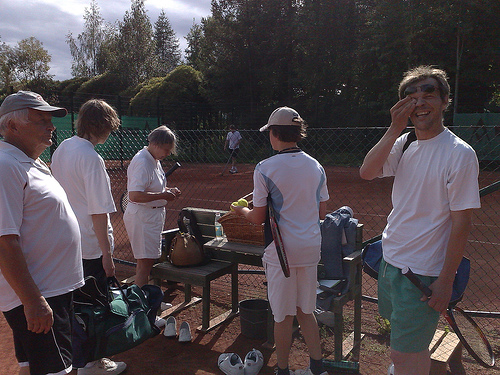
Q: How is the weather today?
A: It is cloudy.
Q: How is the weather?
A: It is cloudy.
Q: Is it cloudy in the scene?
A: Yes, it is cloudy.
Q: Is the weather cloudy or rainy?
A: It is cloudy.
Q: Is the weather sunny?
A: No, it is cloudy.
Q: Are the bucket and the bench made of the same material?
A: Yes, both the bucket and the bench are made of wood.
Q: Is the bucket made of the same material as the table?
A: Yes, both the bucket and the table are made of wood.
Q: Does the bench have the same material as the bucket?
A: Yes, both the bench and the bucket are made of wood.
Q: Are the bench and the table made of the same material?
A: Yes, both the bench and the table are made of wood.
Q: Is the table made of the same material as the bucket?
A: Yes, both the table and the bucket are made of wood.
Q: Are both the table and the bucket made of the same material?
A: Yes, both the table and the bucket are made of wood.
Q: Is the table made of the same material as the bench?
A: Yes, both the table and the bench are made of wood.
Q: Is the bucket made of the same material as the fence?
A: No, the bucket is made of wood and the fence is made of metal.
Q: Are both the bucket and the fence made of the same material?
A: No, the bucket is made of wood and the fence is made of metal.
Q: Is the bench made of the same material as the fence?
A: No, the bench is made of wood and the fence is made of metal.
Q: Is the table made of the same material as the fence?
A: No, the table is made of wood and the fence is made of metal.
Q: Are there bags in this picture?
A: Yes, there is a bag.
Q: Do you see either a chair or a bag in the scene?
A: Yes, there is a bag.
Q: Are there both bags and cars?
A: No, there is a bag but no cars.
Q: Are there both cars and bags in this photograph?
A: No, there is a bag but no cars.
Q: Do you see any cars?
A: No, there are no cars.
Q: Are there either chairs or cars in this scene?
A: No, there are no cars or chairs.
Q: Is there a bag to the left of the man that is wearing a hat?
A: Yes, there is a bag to the left of the man.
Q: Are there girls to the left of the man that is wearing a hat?
A: No, there is a bag to the left of the man.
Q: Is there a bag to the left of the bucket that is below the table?
A: Yes, there is a bag to the left of the bucket.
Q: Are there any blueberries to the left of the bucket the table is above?
A: No, there is a bag to the left of the bucket.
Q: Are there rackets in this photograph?
A: Yes, there is a racket.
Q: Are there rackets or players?
A: Yes, there is a racket.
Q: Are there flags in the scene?
A: No, there are no flags.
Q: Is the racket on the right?
A: Yes, the racket is on the right of the image.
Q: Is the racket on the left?
A: No, the racket is on the right of the image.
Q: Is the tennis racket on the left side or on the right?
A: The tennis racket is on the right of the image.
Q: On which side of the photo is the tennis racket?
A: The tennis racket is on the right of the image.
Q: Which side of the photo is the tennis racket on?
A: The tennis racket is on the right of the image.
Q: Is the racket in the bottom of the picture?
A: Yes, the racket is in the bottom of the image.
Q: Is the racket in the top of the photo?
A: No, the racket is in the bottom of the image.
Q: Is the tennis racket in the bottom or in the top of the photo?
A: The tennis racket is in the bottom of the image.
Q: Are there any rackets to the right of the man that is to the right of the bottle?
A: Yes, there is a racket to the right of the man.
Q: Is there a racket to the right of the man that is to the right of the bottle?
A: Yes, there is a racket to the right of the man.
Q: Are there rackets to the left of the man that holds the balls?
A: No, the racket is to the right of the man.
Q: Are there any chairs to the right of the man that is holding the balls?
A: No, there is a racket to the right of the man.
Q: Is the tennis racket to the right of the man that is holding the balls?
A: Yes, the tennis racket is to the right of the man.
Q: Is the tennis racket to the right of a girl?
A: No, the tennis racket is to the right of the man.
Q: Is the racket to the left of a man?
A: No, the racket is to the right of a man.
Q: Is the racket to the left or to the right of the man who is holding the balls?
A: The racket is to the right of the man.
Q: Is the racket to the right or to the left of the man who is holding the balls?
A: The racket is to the right of the man.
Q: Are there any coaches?
A: No, there are no coaches.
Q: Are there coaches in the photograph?
A: No, there are no coaches.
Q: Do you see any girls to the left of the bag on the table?
A: No, there is a man to the left of the bag.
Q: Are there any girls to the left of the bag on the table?
A: No, there is a man to the left of the bag.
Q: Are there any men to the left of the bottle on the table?
A: Yes, there is a man to the left of the bottle.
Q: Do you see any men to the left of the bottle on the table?
A: Yes, there is a man to the left of the bottle.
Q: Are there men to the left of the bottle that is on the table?
A: Yes, there is a man to the left of the bottle.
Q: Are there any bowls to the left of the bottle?
A: No, there is a man to the left of the bottle.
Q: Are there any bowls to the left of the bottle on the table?
A: No, there is a man to the left of the bottle.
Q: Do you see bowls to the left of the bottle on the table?
A: No, there is a man to the left of the bottle.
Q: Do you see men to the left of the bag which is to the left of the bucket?
A: Yes, there is a man to the left of the bag.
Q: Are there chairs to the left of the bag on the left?
A: No, there is a man to the left of the bag.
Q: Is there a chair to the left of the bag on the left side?
A: No, there is a man to the left of the bag.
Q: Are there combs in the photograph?
A: No, there are no combs.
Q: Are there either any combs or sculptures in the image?
A: No, there are no combs or sculptures.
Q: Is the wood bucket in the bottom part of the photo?
A: Yes, the bucket is in the bottom of the image.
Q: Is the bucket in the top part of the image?
A: No, the bucket is in the bottom of the image.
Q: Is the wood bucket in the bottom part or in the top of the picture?
A: The bucket is in the bottom of the image.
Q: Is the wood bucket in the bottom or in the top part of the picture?
A: The bucket is in the bottom of the image.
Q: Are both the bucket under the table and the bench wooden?
A: Yes, both the bucket and the bench are wooden.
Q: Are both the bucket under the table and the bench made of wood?
A: Yes, both the bucket and the bench are made of wood.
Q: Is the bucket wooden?
A: Yes, the bucket is wooden.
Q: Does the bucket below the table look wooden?
A: Yes, the bucket is wooden.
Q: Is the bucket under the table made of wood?
A: Yes, the bucket is made of wood.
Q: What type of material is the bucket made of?
A: The bucket is made of wood.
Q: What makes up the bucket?
A: The bucket is made of wood.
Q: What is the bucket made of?
A: The bucket is made of wood.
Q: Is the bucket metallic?
A: No, the bucket is wooden.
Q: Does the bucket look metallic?
A: No, the bucket is wooden.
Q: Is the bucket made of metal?
A: No, the bucket is made of wood.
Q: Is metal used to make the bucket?
A: No, the bucket is made of wood.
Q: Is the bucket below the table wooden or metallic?
A: The bucket is wooden.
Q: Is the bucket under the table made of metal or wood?
A: The bucket is made of wood.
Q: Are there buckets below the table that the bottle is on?
A: Yes, there is a bucket below the table.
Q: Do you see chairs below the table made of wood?
A: No, there is a bucket below the table.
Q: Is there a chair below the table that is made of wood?
A: No, there is a bucket below the table.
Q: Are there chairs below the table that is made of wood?
A: No, there is a bucket below the table.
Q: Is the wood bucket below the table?
A: Yes, the bucket is below the table.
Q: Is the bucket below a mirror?
A: No, the bucket is below the table.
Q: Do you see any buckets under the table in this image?
A: Yes, there is a bucket under the table.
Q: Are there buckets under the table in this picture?
A: Yes, there is a bucket under the table.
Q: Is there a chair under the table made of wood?
A: No, there is a bucket under the table.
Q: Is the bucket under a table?
A: Yes, the bucket is under a table.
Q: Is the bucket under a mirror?
A: No, the bucket is under a table.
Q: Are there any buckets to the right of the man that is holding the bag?
A: Yes, there is a bucket to the right of the man.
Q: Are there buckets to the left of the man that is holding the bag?
A: No, the bucket is to the right of the man.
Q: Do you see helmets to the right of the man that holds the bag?
A: No, there is a bucket to the right of the man.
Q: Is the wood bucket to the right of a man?
A: Yes, the bucket is to the right of a man.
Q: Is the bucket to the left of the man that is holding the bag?
A: No, the bucket is to the right of the man.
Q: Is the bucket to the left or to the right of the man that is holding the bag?
A: The bucket is to the right of the man.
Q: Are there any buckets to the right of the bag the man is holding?
A: Yes, there is a bucket to the right of the bag.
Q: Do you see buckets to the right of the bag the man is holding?
A: Yes, there is a bucket to the right of the bag.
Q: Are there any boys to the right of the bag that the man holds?
A: No, there is a bucket to the right of the bag.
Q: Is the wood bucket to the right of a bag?
A: Yes, the bucket is to the right of a bag.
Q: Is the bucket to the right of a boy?
A: No, the bucket is to the right of a bag.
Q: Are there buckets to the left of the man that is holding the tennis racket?
A: Yes, there is a bucket to the left of the man.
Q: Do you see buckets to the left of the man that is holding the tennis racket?
A: Yes, there is a bucket to the left of the man.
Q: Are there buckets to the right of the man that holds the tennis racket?
A: No, the bucket is to the left of the man.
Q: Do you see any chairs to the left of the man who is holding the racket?
A: No, there is a bucket to the left of the man.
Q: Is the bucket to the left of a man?
A: Yes, the bucket is to the left of a man.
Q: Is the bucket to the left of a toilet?
A: No, the bucket is to the left of a man.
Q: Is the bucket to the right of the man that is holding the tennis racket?
A: No, the bucket is to the left of the man.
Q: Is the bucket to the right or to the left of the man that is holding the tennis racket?
A: The bucket is to the left of the man.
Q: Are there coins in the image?
A: No, there are no coins.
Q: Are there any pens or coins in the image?
A: No, there are no coins or pens.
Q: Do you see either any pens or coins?
A: No, there are no coins or pens.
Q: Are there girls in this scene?
A: No, there are no girls.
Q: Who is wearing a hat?
A: The man is wearing a hat.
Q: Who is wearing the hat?
A: The man is wearing a hat.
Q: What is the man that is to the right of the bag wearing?
A: The man is wearing a hat.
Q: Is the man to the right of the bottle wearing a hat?
A: Yes, the man is wearing a hat.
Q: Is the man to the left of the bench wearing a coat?
A: No, the man is wearing a hat.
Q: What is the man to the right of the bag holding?
A: The man is holding the balls.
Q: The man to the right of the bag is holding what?
A: The man is holding the balls.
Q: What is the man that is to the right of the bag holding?
A: The man is holding the balls.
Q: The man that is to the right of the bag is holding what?
A: The man is holding the balls.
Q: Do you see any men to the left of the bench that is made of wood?
A: Yes, there is a man to the left of the bench.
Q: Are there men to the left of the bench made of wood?
A: Yes, there is a man to the left of the bench.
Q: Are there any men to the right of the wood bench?
A: No, the man is to the left of the bench.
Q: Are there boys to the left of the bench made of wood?
A: No, there is a man to the left of the bench.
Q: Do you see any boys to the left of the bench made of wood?
A: No, there is a man to the left of the bench.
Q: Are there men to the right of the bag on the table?
A: Yes, there is a man to the right of the bag.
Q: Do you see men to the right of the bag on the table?
A: Yes, there is a man to the right of the bag.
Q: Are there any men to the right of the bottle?
A: Yes, there is a man to the right of the bottle.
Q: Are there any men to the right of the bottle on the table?
A: Yes, there is a man to the right of the bottle.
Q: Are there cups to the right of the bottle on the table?
A: No, there is a man to the right of the bottle.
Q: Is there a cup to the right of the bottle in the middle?
A: No, there is a man to the right of the bottle.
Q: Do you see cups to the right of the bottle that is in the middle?
A: No, there is a man to the right of the bottle.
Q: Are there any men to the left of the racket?
A: Yes, there is a man to the left of the racket.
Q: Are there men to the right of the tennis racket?
A: No, the man is to the left of the tennis racket.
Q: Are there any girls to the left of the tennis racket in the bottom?
A: No, there is a man to the left of the racket.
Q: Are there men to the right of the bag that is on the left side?
A: Yes, there is a man to the right of the bag.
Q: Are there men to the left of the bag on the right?
A: Yes, there is a man to the left of the bag.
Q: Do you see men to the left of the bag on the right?
A: Yes, there is a man to the left of the bag.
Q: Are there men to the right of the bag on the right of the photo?
A: No, the man is to the left of the bag.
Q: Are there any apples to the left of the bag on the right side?
A: No, there is a man to the left of the bag.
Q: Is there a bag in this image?
A: Yes, there is a bag.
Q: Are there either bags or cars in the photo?
A: Yes, there is a bag.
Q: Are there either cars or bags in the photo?
A: Yes, there is a bag.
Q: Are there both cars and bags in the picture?
A: No, there is a bag but no cars.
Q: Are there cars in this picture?
A: No, there are no cars.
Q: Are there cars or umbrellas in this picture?
A: No, there are no cars or umbrellas.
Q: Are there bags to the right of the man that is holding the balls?
A: Yes, there is a bag to the right of the man.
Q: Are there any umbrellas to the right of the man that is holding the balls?
A: No, there is a bag to the right of the man.